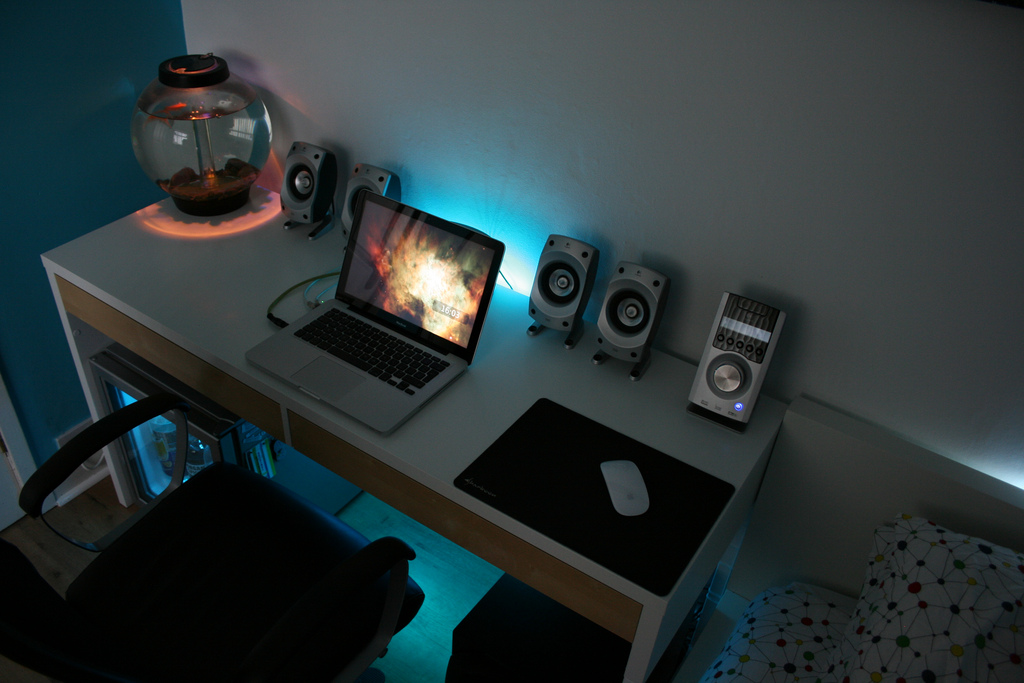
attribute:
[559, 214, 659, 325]
speaker — white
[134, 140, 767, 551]
desk — white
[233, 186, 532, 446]
laptop — silver, black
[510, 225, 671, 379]
speakers — silver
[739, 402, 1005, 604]
frame — white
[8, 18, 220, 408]
wall — blue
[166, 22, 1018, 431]
wall — white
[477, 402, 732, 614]
mousepad — black, rectangular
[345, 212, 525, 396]
screensaver — fiery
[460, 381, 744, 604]
mousepad — black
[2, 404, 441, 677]
office chair — black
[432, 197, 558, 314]
glow — blue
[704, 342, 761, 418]
dial — circle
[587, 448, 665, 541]
mouse — white, wireless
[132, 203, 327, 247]
glow — orange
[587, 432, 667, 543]
mouse — white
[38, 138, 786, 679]
desk — white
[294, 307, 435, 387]
keys — black